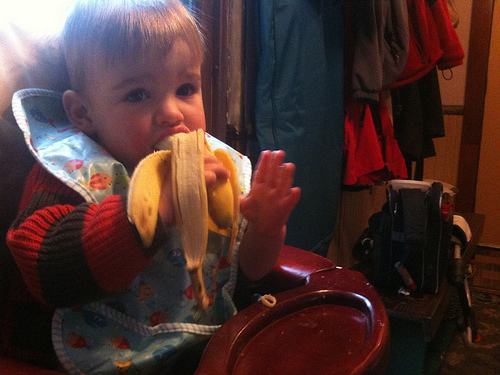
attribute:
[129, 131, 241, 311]
banana peel — stringy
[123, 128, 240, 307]
banana — peeled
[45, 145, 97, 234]
sweater — red, black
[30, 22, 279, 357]
child — young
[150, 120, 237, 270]
banana — yellow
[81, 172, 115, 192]
goldfish — orange, cartoon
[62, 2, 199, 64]
hair — light brown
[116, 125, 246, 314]
banana — yellow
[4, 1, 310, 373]
boy — young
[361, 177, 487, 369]
bench — wooden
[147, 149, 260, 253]
banana — peeled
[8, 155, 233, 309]
baby's arm — bent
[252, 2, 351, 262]
bag — blue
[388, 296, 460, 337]
bench — dark brown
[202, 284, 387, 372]
tray — red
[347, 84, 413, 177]
garment — hanging, red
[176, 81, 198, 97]
eye — brown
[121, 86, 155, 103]
eye — brown